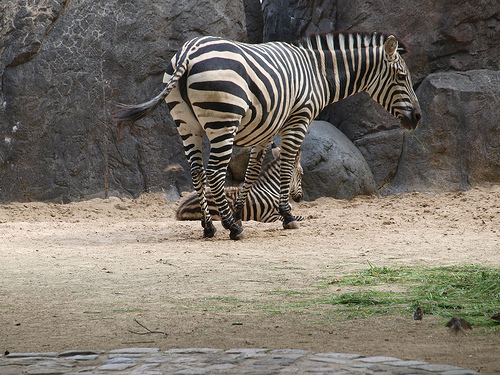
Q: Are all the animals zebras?
A: No, there are both zebras and birds.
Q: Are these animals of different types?
A: Yes, they are zebras and birds.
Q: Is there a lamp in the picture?
A: No, there are no lamps.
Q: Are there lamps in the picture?
A: No, there are no lamps.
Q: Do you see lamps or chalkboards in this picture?
A: No, there are no lamps or chalkboards.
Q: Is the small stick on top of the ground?
A: Yes, the stick is on top of the ground.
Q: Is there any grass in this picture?
A: Yes, there is grass.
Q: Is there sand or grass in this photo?
A: Yes, there is grass.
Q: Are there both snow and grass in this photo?
A: No, there is grass but no snow.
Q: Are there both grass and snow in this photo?
A: No, there is grass but no snow.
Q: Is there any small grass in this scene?
A: Yes, there is small grass.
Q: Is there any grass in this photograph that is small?
A: Yes, there is grass that is small.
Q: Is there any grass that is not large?
A: Yes, there is small grass.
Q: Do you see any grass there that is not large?
A: Yes, there is small grass.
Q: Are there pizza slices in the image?
A: No, there are no pizza slices.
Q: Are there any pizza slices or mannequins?
A: No, there are no pizza slices or mannequins.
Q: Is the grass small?
A: Yes, the grass is small.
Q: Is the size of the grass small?
A: Yes, the grass is small.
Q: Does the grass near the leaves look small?
A: Yes, the grass is small.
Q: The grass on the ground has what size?
A: The grass is small.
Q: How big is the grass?
A: The grass is small.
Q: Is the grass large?
A: No, the grass is small.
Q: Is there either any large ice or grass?
A: No, there is grass but it is small.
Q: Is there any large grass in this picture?
A: No, there is grass but it is small.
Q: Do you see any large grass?
A: No, there is grass but it is small.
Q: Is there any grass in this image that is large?
A: No, there is grass but it is small.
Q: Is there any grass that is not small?
A: No, there is grass but it is small.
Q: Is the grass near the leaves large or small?
A: The grass is small.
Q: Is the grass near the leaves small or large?
A: The grass is small.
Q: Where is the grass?
A: The grass is on the ground.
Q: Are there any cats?
A: No, there are no cats.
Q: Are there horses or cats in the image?
A: No, there are no cats or horses.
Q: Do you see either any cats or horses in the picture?
A: No, there are no cats or horses.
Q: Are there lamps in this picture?
A: No, there are no lamps.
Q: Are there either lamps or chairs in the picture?
A: No, there are no lamps or chairs.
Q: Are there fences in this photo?
A: No, there are no fences.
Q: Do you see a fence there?
A: No, there are no fences.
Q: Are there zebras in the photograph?
A: Yes, there is a zebra.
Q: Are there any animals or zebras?
A: Yes, there is a zebra.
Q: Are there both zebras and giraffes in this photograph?
A: No, there is a zebra but no giraffes.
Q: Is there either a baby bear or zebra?
A: Yes, there is a baby zebra.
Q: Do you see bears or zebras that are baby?
A: Yes, the zebra is a baby.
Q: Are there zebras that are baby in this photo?
A: Yes, there is a baby zebra.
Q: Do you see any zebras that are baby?
A: Yes, there is a zebra that is a baby.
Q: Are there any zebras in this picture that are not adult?
A: Yes, there is an baby zebra.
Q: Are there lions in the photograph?
A: No, there are no lions.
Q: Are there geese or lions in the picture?
A: No, there are no lions or geese.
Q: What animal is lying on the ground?
A: The zebra is lying on the ground.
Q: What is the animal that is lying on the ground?
A: The animal is a zebra.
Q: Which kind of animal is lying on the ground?
A: The animal is a zebra.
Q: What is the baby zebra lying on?
A: The zebra is lying on the ground.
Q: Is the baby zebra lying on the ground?
A: Yes, the zebra is lying on the ground.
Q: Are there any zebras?
A: Yes, there is a zebra.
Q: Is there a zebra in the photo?
A: Yes, there is a zebra.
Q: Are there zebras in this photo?
A: Yes, there is a zebra.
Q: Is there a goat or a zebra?
A: Yes, there is a zebra.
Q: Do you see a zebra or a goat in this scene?
A: Yes, there is a zebra.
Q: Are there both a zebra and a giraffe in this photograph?
A: No, there is a zebra but no giraffes.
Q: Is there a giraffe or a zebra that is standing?
A: Yes, the zebra is standing.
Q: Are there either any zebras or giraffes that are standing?
A: Yes, the zebra is standing.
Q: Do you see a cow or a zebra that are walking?
A: Yes, the zebra is walking.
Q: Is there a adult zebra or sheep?
A: Yes, there is an adult zebra.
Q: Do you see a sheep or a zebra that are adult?
A: Yes, the zebra is adult.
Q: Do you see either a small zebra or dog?
A: Yes, there is a small zebra.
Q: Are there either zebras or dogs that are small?
A: Yes, the zebra is small.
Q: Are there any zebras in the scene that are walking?
A: Yes, there is a zebra that is walking.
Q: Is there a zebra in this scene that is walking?
A: Yes, there is a zebra that is walking.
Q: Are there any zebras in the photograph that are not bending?
A: Yes, there is a zebra that is walking.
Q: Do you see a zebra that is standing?
A: Yes, there is a zebra that is standing.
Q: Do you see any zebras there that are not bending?
A: Yes, there is a zebra that is standing .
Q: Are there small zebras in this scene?
A: Yes, there is a small zebra.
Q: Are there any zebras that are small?
A: Yes, there is a zebra that is small.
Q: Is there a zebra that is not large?
A: Yes, there is a small zebra.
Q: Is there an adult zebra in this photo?
A: Yes, there is an adult zebra.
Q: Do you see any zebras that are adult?
A: Yes, there is a zebra that is adult.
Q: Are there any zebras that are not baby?
A: Yes, there is a adult zebra.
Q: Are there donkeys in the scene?
A: No, there are no donkeys.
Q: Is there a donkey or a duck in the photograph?
A: No, there are no donkeys or ducks.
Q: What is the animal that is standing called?
A: The animal is a zebra.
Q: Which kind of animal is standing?
A: The animal is a zebra.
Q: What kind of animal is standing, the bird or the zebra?
A: The zebra is standing.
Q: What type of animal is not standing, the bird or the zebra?
A: The bird is not standing.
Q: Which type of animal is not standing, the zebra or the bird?
A: The bird is not standing.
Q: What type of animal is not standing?
A: The animal is a bird.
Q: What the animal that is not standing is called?
A: The animal is a bird.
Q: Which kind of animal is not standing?
A: The animal is a bird.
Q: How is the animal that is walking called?
A: The animal is a zebra.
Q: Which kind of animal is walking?
A: The animal is a zebra.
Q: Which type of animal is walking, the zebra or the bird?
A: The zebra is walking.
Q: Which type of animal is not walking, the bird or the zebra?
A: The bird is not walking.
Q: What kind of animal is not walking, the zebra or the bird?
A: The bird is not walking.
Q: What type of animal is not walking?
A: The animal is a bird.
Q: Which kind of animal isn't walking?
A: The animal is a bird.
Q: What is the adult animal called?
A: The animal is a zebra.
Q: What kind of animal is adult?
A: The animal is a zebra.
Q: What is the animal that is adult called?
A: The animal is a zebra.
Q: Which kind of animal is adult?
A: The animal is a zebra.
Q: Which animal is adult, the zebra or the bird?
A: The zebra is adult.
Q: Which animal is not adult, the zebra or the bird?
A: The bird is not adult.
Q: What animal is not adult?
A: The animal is a bird.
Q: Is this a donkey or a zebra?
A: This is a zebra.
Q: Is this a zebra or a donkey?
A: This is a zebra.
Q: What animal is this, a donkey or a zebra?
A: This is a zebra.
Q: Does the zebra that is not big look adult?
A: Yes, the zebra is adult.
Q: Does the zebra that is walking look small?
A: Yes, the zebra is small.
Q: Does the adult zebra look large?
A: No, the zebra is small.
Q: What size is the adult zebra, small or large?
A: The zebra is small.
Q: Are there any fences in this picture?
A: No, there are no fences.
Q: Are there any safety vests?
A: No, there are no safety vests.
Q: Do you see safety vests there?
A: No, there are no safety vests.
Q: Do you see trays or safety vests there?
A: No, there are no safety vests or trays.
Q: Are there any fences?
A: No, there are no fences.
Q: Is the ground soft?
A: Yes, the ground is soft.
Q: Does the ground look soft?
A: Yes, the ground is soft.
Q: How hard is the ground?
A: The ground is soft.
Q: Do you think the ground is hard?
A: No, the ground is soft.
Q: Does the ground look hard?
A: No, the ground is soft.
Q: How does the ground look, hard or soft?
A: The ground is soft.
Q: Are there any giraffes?
A: No, there are no giraffes.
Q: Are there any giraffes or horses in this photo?
A: No, there are no giraffes or horses.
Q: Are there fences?
A: No, there are no fences.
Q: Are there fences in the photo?
A: No, there are no fences.